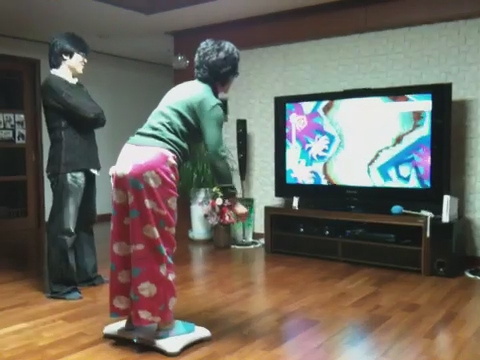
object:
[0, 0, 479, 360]
room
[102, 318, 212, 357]
board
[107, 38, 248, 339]
woman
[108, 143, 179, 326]
pants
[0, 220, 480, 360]
floor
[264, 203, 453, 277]
stand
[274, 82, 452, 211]
tv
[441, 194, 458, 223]
console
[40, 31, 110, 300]
man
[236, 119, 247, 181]
speaker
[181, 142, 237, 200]
plant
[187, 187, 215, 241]
pot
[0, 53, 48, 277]
door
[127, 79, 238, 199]
shirt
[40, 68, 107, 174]
shirt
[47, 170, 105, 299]
pants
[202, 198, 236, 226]
flowers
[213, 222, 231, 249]
pot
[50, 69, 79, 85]
collar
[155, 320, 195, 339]
sock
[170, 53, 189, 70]
fixture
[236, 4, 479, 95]
wall